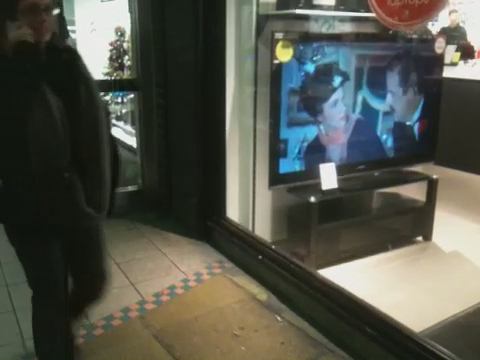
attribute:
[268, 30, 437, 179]
tv — flat screen, flat, black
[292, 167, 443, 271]
cabinet — black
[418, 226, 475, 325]
flooring — tile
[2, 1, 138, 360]
person — walking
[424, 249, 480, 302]
floor — tan, tiled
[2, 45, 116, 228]
jacket — black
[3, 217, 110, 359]
pants — black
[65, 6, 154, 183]
window — storefront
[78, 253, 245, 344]
tile — blue, pink, beige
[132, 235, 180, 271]
tile — brown